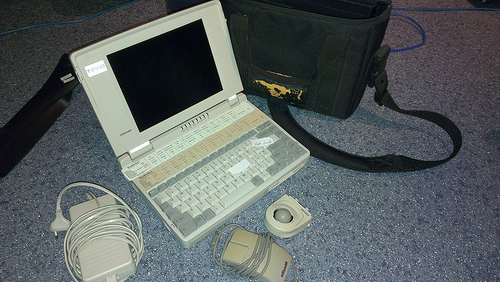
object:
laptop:
[59, 0, 331, 246]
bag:
[226, 2, 392, 119]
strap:
[265, 87, 466, 173]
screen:
[99, 18, 220, 134]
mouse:
[215, 227, 294, 282]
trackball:
[271, 207, 293, 224]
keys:
[174, 187, 190, 203]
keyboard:
[123, 102, 312, 244]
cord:
[212, 223, 275, 280]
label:
[80, 60, 110, 77]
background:
[2, 0, 500, 63]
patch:
[245, 70, 308, 103]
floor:
[0, 0, 500, 281]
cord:
[17, 3, 135, 36]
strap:
[0, 54, 72, 180]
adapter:
[66, 193, 136, 281]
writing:
[279, 260, 291, 277]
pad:
[261, 243, 288, 282]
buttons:
[220, 243, 247, 262]